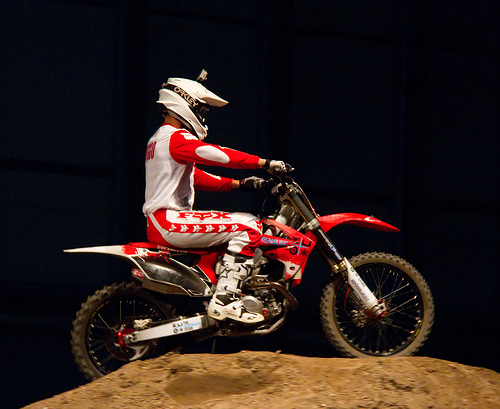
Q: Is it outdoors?
A: Yes, it is outdoors.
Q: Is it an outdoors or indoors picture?
A: It is outdoors.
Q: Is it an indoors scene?
A: No, it is outdoors.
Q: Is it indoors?
A: No, it is outdoors.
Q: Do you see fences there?
A: No, there are no fences.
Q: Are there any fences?
A: No, there are no fences.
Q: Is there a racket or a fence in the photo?
A: No, there are no fences or rackets.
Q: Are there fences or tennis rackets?
A: No, there are no fences or tennis rackets.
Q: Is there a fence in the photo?
A: No, there are no fences.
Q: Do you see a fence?
A: No, there are no fences.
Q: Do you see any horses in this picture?
A: No, there are no horses.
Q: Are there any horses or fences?
A: No, there are no horses or fences.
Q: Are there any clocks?
A: No, there are no clocks.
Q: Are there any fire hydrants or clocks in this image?
A: No, there are no clocks or fire hydrants.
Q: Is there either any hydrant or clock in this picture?
A: No, there are no clocks or fire hydrants.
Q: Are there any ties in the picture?
A: No, there are no ties.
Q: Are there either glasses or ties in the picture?
A: No, there are no ties or glasses.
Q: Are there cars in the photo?
A: No, there are no cars.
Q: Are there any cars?
A: No, there are no cars.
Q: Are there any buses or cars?
A: No, there are no cars or buses.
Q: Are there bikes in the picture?
A: Yes, there is a bike.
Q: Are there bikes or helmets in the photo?
A: Yes, there is a bike.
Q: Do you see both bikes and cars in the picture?
A: No, there is a bike but no cars.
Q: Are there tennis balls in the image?
A: No, there are no tennis balls.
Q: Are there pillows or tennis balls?
A: No, there are no tennis balls or pillows.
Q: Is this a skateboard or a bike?
A: This is a bike.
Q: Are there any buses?
A: No, there are no buses.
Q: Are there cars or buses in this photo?
A: No, there are no buses or cars.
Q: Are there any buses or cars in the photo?
A: No, there are no buses or cars.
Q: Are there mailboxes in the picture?
A: No, there are no mailboxes.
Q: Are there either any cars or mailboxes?
A: No, there are no mailboxes or cars.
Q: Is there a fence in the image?
A: No, there are no fences.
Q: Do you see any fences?
A: No, there are no fences.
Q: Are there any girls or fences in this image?
A: No, there are no fences or girls.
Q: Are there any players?
A: No, there are no players.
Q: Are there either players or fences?
A: No, there are no players or fences.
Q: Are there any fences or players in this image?
A: No, there are no players or fences.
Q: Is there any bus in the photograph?
A: No, there are no buses.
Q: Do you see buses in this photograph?
A: No, there are no buses.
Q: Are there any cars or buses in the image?
A: No, there are no buses or cars.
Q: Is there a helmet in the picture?
A: Yes, there is a helmet.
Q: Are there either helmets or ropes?
A: Yes, there is a helmet.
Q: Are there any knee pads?
A: No, there are no knee pads.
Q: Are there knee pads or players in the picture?
A: No, there are no knee pads or players.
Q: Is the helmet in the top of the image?
A: Yes, the helmet is in the top of the image.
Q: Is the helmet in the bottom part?
A: No, the helmet is in the top of the image.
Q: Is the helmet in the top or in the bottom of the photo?
A: The helmet is in the top of the image.